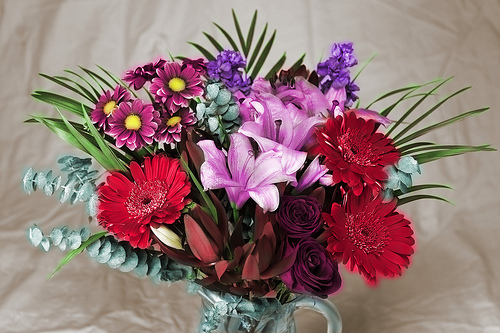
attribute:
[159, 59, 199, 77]
petals — pointy, purple, curving outwards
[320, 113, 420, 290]
gerbera — red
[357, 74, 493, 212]
blades — thin, long, green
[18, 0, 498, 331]
roses — purple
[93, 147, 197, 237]
flower — red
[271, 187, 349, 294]
clusters — small, tight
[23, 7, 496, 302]
flowers —   red, fresh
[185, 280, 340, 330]
pitcher — silver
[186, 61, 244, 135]
foliage — green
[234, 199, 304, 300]
flower — maroon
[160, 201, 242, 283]
flower — maroon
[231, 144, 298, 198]
petals —  purple, with white edges,  with yellow center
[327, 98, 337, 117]
stem —  purple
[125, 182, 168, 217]
spots —  white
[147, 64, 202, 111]
flower —  yellow inside 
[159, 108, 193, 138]
flower —  yellow inside 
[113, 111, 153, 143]
flower —  yellow inside 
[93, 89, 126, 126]
flower —  yellow inside 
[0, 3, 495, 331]
fabric — white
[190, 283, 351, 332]
vase — blue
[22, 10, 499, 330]
combination —  floral ,  of shapes and colors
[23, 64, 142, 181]
leaves — green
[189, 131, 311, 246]
flower —  pink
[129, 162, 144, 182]
petal — oval, red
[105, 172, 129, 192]
petal — red, oval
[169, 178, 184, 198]
petal — oval, red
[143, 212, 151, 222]
petal — red, oval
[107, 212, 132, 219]
petal — oval, red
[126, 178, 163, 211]
circle — red, white, fuzzy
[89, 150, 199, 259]
flower — red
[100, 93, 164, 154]
flower — red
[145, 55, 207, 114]
flower — red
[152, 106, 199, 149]
flower — red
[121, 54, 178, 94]
flower — red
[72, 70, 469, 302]
flowers —  green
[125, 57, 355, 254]
flowers — purple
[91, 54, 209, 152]
chrysanthemums —  purple, yellow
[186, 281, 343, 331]
pitcher vase — blue, ceramic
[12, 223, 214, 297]
foliage — grey-green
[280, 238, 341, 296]
rose — deep purple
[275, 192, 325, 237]
rose — deep purple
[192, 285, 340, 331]
jug — glass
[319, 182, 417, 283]
gerbera — deep red 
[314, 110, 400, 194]
gerbera — deep red 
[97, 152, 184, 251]
gerbera — deep red 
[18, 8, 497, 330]
bouquet —  of flowers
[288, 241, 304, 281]
petals — maroon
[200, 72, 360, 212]
flowers — lavender